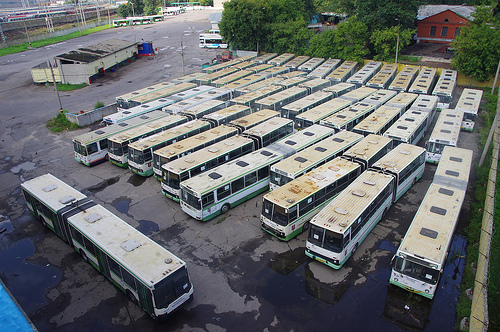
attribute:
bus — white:
[72, 203, 196, 316]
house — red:
[415, 4, 474, 51]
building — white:
[402, 0, 494, 61]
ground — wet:
[285, 267, 369, 309]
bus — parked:
[388, 177, 467, 312]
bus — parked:
[305, 165, 394, 270]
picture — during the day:
[185, 42, 465, 282]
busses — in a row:
[386, 143, 476, 301]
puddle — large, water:
[279, 282, 394, 317]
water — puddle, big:
[219, 285, 357, 326]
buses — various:
[57, 32, 409, 250]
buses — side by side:
[209, 61, 234, 92]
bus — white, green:
[179, 145, 284, 223]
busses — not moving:
[20, 50, 482, 316]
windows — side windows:
[213, 179, 232, 200]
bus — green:
[164, 120, 336, 221]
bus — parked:
[180, 121, 331, 220]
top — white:
[68, 202, 189, 283]